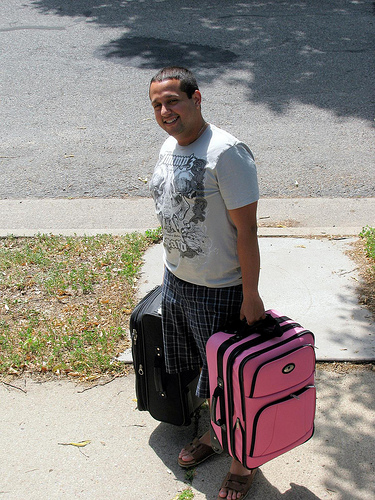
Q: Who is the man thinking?
A: How great his trip will be.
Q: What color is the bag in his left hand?
A: Pink.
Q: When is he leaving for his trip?
A: Right now.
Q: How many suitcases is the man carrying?
A: Two.